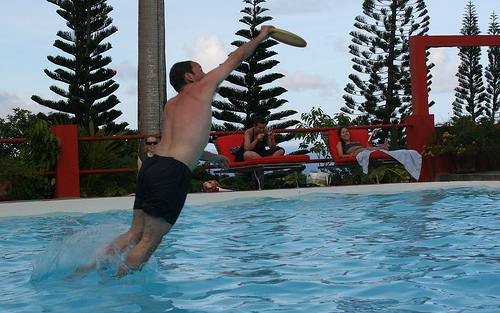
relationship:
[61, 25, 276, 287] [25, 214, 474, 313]
male in pool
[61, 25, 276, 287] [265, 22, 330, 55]
male catching frisbee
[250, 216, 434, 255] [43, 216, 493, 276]
ripples in water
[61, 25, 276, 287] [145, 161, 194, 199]
male wearing shorts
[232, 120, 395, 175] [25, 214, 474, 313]
people beside pool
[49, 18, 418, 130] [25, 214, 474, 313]
trees by pool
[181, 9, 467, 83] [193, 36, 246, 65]
sky has clouds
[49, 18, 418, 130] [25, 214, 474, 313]
trees behind pool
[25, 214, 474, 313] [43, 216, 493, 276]
pool has water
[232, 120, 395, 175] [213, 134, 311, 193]
people in chairs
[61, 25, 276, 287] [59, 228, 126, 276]
male in water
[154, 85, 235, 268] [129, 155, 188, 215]
male wearing trunks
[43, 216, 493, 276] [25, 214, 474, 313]
water in pool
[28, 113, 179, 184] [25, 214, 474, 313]
fence around pool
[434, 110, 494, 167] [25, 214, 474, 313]
entry to pool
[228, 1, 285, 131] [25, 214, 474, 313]
tree outside pool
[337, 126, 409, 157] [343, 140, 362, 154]
people in bathing suit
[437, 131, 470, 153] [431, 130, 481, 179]
flowers on plant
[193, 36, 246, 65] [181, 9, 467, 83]
clouds in sky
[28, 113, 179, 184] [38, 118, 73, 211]
fence has poles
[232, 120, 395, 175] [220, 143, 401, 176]
people on chairs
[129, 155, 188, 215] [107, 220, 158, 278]
trunks on legs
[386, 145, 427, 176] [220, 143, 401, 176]
towel on chairs